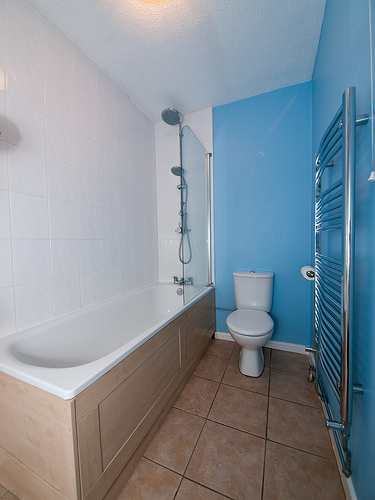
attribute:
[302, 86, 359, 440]
framework — wired, metal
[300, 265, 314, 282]
paper — toilet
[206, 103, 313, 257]
wall — blue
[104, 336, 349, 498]
flooring — tiled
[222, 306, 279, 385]
toilet — white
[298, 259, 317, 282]
toilet paper — white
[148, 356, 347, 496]
tile floor — ceramic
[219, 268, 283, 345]
toilet bowl — white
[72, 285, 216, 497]
wood portion — small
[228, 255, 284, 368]
toilet — clean, closed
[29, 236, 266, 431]
tub — empty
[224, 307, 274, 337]
seat — down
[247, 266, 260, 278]
buttons — flush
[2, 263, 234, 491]
bathtub — white, porcelain